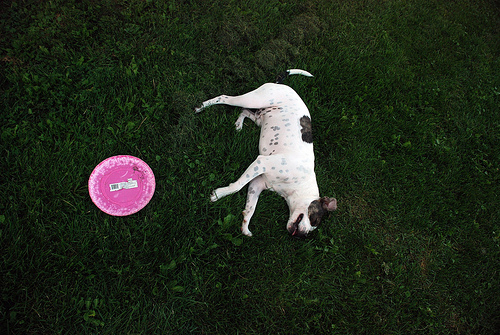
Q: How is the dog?
A: Lying.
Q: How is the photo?
A: Clear.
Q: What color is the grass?
A: Green.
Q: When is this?
A: Daytime.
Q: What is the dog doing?
A: Resting.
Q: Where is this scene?
A: On a lawn.